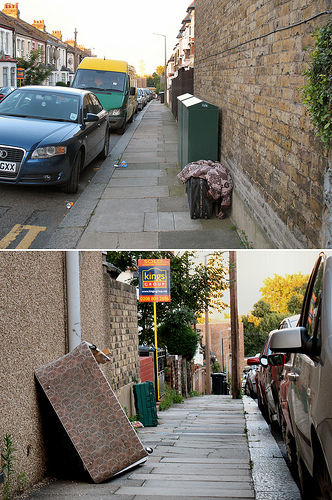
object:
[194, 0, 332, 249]
building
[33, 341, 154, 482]
furniture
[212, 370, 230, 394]
garbagebins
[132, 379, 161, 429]
bin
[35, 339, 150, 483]
piece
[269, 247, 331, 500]
cars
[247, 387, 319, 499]
road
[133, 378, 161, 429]
box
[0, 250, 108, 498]
wall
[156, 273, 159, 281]
yellow letter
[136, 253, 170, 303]
sign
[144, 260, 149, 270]
letter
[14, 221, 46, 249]
paint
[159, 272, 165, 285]
letter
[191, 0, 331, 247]
wall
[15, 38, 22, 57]
window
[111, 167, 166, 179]
tile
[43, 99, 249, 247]
pavement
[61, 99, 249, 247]
sidewalk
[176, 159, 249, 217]
clothing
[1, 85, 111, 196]
car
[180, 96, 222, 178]
bins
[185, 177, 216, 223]
suitcase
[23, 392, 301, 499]
sidewalk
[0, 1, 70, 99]
building